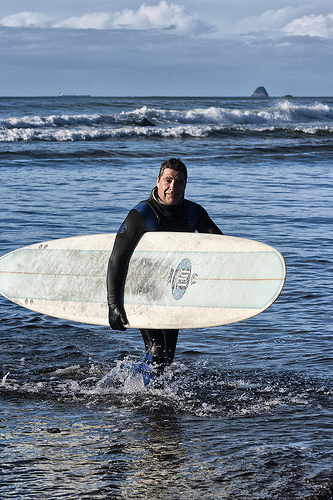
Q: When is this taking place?
A: Daytime.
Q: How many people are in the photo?
A: One.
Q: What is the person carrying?
A: Surfboard.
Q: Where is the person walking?
A: Water.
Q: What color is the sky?
A: Blue.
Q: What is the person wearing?
A: Wetsuit.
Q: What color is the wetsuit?
A: Black.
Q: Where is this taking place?
A: In the ocean.